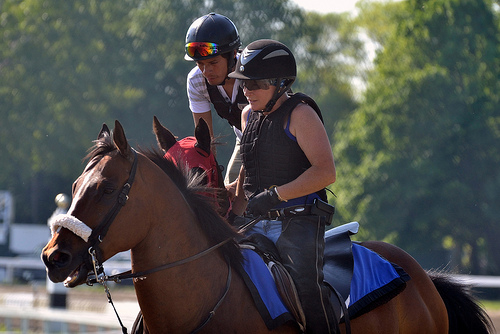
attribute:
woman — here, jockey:
[244, 53, 306, 236]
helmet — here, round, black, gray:
[242, 43, 319, 65]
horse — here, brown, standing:
[5, 194, 418, 310]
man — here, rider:
[179, 8, 234, 112]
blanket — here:
[366, 262, 376, 277]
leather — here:
[187, 301, 252, 327]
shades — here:
[245, 85, 258, 91]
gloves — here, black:
[231, 193, 284, 214]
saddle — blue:
[243, 252, 265, 272]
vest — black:
[252, 144, 275, 173]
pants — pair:
[281, 214, 317, 276]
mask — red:
[172, 149, 191, 162]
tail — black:
[457, 297, 478, 319]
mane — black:
[164, 179, 193, 214]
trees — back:
[399, 0, 440, 51]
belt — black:
[289, 201, 311, 214]